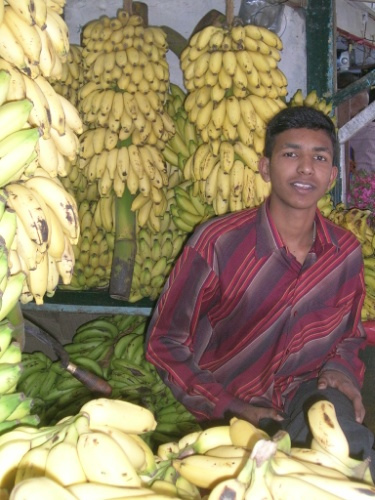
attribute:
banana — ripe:
[306, 400, 348, 457]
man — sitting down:
[149, 92, 372, 435]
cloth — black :
[291, 377, 372, 463]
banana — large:
[31, 76, 65, 138]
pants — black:
[286, 383, 355, 443]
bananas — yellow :
[0, 398, 374, 499]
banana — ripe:
[21, 71, 56, 141]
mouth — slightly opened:
[290, 177, 319, 196]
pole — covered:
[108, 182, 136, 301]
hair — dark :
[267, 106, 339, 145]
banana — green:
[138, 235, 154, 260]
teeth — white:
[291, 180, 316, 191]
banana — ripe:
[74, 399, 159, 440]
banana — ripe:
[29, 173, 86, 242]